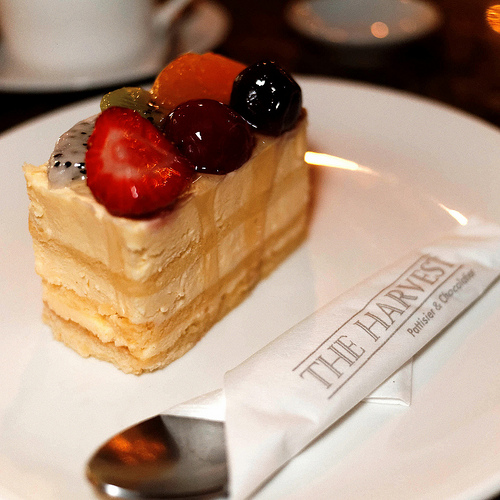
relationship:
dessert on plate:
[13, 373, 499, 492] [8, 82, 496, 490]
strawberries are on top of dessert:
[46, 115, 194, 212] [13, 373, 499, 492]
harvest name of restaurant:
[292, 245, 454, 405] [8, 82, 496, 490]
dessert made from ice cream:
[13, 373, 499, 492] [63, 221, 251, 363]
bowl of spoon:
[117, 419, 224, 487] [85, 244, 482, 499]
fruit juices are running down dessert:
[206, 184, 220, 325] [13, 373, 499, 492]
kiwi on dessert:
[97, 80, 170, 117] [13, 373, 499, 492]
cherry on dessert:
[156, 96, 264, 172] [13, 373, 499, 492]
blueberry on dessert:
[221, 56, 325, 137] [13, 373, 499, 492]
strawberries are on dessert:
[46, 115, 194, 212] [13, 373, 499, 492]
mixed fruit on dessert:
[43, 49, 308, 218] [13, 373, 499, 492]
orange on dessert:
[153, 44, 263, 109] [13, 373, 499, 492]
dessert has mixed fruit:
[13, 373, 499, 492] [43, 49, 308, 218]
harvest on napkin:
[292, 245, 454, 405] [236, 287, 446, 479]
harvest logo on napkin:
[292, 245, 454, 405] [236, 287, 446, 479]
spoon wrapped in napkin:
[85, 244, 482, 499] [236, 287, 446, 479]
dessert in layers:
[13, 373, 499, 492] [45, 314, 149, 367]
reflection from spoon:
[115, 434, 173, 463] [85, 244, 482, 499]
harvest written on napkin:
[292, 245, 454, 405] [236, 287, 446, 479]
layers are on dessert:
[45, 314, 149, 367] [13, 373, 499, 492]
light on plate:
[308, 147, 375, 179] [8, 82, 496, 490]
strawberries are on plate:
[46, 115, 194, 212] [8, 82, 496, 490]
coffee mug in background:
[4, 1, 194, 83] [5, 5, 500, 103]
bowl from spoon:
[117, 419, 224, 487] [85, 244, 482, 499]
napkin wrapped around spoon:
[236, 287, 446, 479] [85, 244, 482, 499]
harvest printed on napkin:
[292, 245, 454, 405] [236, 287, 446, 479]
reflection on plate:
[115, 434, 173, 463] [8, 82, 496, 490]